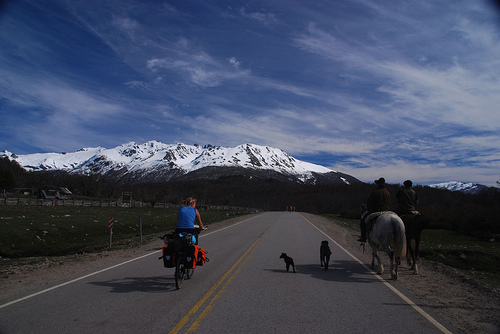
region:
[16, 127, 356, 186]
Snowy mountains in the background.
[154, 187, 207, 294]
Woman riding bicycle on the road.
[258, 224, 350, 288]
Two dogs in the road.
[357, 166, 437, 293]
Two people riding horses on side of road.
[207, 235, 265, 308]
Yellow lines in the street.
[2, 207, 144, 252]
Grassy area along side of road.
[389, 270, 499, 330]
Dirt path along side of road.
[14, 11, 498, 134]
Blue sky with clouds.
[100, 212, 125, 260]
Road sign on the grass.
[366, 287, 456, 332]
White line on the road.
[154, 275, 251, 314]
double yellow lines in road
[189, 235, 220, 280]
red bag on bike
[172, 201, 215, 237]
man wearing blue shirt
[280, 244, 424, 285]
shadows in the road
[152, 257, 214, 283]
wheel on bike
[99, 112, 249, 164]
snow covered mountain range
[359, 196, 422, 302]
large animal at side of road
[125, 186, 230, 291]
man riding small bike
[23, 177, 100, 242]
green bushes at side of road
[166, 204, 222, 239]
the woman has blue top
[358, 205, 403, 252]
the horse is white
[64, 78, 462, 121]
the sky is blue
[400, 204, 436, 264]
the horse is brown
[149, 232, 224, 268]
the bags are orange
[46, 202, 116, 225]
the grass is green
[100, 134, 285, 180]
there is snow on the hills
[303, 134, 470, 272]
there are two people on the horse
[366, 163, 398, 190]
the hat is black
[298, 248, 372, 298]
there is shadow on the ground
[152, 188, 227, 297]
Person riding a bike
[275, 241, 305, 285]
Animal in the middle of the road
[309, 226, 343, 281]
Animal walking in the road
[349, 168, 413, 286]
Person riding a horse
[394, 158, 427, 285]
Person riding a horse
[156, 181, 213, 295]
Person wearing a blue shirt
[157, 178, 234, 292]
Person wearing a blue shirt and riding a bike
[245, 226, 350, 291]
Two animals walking in the road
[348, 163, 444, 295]
Two people riding horses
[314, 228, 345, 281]
Dog walking in the road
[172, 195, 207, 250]
this is a woman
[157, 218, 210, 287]
the woman is on a bike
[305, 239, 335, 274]
this is a dog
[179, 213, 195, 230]
the woman is wearing blue top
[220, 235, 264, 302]
the road has yellow strip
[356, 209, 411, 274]
this is a horse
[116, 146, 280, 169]
the mountain is full of snow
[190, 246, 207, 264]
a red bag is beside the bike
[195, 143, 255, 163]
the snow is white in color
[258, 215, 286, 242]
the road is tarmacked